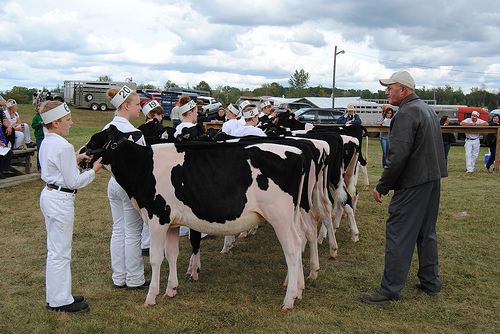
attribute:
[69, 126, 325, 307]
cow — black, white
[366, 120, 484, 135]
table — wooden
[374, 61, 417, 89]
hat — grey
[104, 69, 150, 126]
head — red